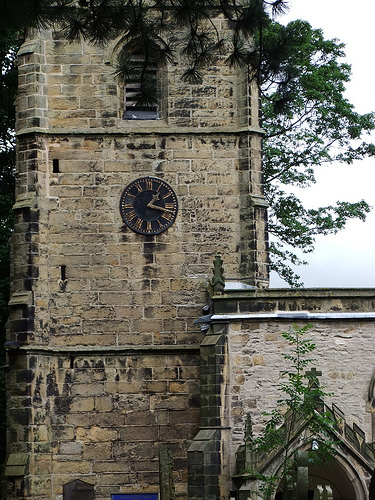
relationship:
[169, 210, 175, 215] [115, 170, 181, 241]
minute hand on clock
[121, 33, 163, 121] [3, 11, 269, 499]
window on building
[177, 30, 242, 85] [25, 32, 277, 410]
leaves are covering tower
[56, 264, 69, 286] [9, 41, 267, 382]
hole in tower wall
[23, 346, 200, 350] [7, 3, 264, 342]
ledge on tower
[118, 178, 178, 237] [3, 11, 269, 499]
clock on building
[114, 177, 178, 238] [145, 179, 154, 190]
clock has numeral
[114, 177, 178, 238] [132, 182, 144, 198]
clock has numeral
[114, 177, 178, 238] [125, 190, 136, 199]
clock has numeral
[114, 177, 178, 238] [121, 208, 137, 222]
clock has numeral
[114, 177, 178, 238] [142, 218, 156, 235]
clock has numeral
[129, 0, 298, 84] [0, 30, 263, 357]
tree behind a tower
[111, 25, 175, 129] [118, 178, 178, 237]
building window over a clock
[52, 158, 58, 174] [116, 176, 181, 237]
opening on left side of clock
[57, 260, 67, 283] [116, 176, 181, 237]
opening on left side of clock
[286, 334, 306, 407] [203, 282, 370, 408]
tree in front of building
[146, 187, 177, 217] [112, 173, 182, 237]
gold hands on clock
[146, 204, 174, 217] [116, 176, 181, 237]
gold hands on clock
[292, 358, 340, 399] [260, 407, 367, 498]
cross over doorway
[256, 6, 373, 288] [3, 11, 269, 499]
trees behind building